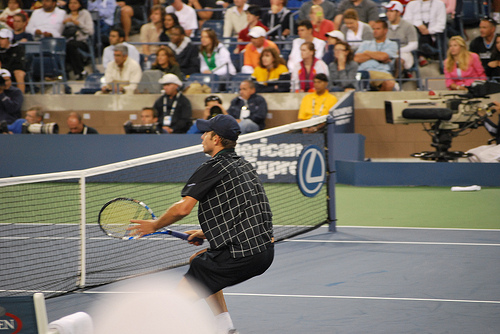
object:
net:
[0, 117, 332, 302]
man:
[128, 114, 273, 333]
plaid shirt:
[179, 147, 274, 258]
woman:
[441, 35, 487, 92]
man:
[148, 73, 193, 135]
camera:
[377, 83, 500, 163]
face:
[198, 128, 213, 153]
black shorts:
[183, 243, 273, 298]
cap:
[191, 114, 241, 142]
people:
[1, 2, 496, 132]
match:
[3, 102, 495, 328]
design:
[295, 143, 327, 197]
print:
[240, 139, 306, 181]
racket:
[97, 197, 204, 246]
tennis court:
[0, 180, 498, 330]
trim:
[2, 113, 329, 198]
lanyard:
[160, 90, 181, 126]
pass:
[162, 115, 172, 126]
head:
[200, 118, 238, 158]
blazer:
[442, 50, 484, 90]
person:
[290, 40, 326, 95]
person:
[246, 49, 292, 90]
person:
[193, 26, 236, 89]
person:
[98, 43, 142, 96]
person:
[350, 19, 399, 89]